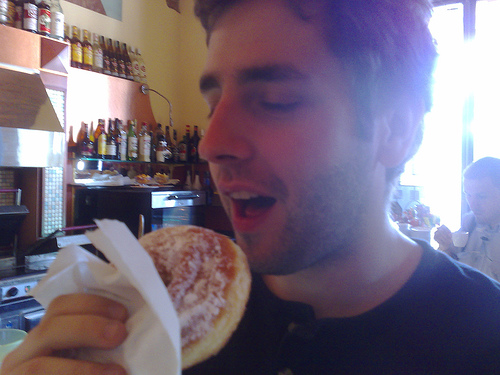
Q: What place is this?
A: It is a restaurant.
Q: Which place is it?
A: It is a restaurant.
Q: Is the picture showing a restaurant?
A: Yes, it is showing a restaurant.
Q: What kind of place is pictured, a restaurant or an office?
A: It is a restaurant.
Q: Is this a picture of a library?
A: No, the picture is showing a restaurant.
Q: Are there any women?
A: No, there are no women.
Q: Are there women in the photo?
A: No, there are no women.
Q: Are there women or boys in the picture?
A: No, there are no women or boys.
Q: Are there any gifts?
A: No, there are no gifts.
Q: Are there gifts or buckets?
A: No, there are no gifts or buckets.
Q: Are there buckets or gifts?
A: No, there are no gifts or buckets.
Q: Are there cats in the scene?
A: No, there are no cats.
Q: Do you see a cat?
A: No, there are no cats.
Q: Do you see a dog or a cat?
A: No, there are no cats or dogs.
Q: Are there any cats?
A: No, there are no cats.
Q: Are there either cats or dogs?
A: No, there are no cats or dogs.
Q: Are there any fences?
A: No, there are no fences.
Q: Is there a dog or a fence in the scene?
A: No, there are no fences or dogs.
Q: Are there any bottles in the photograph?
A: Yes, there is a bottle.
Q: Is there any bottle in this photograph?
A: Yes, there is a bottle.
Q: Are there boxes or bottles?
A: Yes, there is a bottle.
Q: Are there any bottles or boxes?
A: Yes, there is a bottle.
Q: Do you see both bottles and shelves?
A: Yes, there are both a bottle and a shelf.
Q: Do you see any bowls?
A: No, there are no bowls.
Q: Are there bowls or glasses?
A: No, there are no bowls or glasses.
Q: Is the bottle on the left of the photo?
A: Yes, the bottle is on the left of the image.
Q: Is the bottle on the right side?
A: No, the bottle is on the left of the image.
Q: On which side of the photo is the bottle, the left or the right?
A: The bottle is on the left of the image.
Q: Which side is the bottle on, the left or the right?
A: The bottle is on the left of the image.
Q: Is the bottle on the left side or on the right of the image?
A: The bottle is on the left of the image.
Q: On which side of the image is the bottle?
A: The bottle is on the left of the image.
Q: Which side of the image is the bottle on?
A: The bottle is on the left of the image.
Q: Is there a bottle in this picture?
A: Yes, there is a bottle.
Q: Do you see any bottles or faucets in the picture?
A: Yes, there is a bottle.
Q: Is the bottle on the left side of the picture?
A: Yes, the bottle is on the left of the image.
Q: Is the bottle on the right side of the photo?
A: No, the bottle is on the left of the image.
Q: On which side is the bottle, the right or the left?
A: The bottle is on the left of the image.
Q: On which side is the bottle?
A: The bottle is on the left of the image.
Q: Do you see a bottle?
A: Yes, there is a bottle.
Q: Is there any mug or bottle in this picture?
A: Yes, there is a bottle.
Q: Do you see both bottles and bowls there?
A: No, there is a bottle but no bowls.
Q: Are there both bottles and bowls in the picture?
A: No, there is a bottle but no bowls.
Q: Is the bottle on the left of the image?
A: Yes, the bottle is on the left of the image.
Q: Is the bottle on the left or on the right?
A: The bottle is on the left of the image.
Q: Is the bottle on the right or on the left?
A: The bottle is on the left of the image.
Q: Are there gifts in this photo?
A: No, there are no gifts.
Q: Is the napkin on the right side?
A: No, the napkin is on the left of the image.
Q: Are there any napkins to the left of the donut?
A: Yes, there is a napkin to the left of the donut.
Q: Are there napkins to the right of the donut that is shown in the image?
A: No, the napkin is to the left of the donut.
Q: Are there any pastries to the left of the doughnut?
A: No, there is a napkin to the left of the doughnut.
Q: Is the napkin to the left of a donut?
A: Yes, the napkin is to the left of a donut.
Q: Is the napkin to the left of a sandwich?
A: No, the napkin is to the left of a donut.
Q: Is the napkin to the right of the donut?
A: No, the napkin is to the left of the donut.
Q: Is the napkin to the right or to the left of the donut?
A: The napkin is to the left of the donut.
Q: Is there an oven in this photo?
A: Yes, there is an oven.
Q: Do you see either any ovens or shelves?
A: Yes, there is an oven.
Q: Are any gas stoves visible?
A: No, there are no gas stoves.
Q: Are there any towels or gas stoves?
A: No, there are no gas stoves or towels.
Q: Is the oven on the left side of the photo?
A: Yes, the oven is on the left of the image.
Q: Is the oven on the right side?
A: No, the oven is on the left of the image.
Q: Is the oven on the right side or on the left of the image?
A: The oven is on the left of the image.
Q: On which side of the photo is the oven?
A: The oven is on the left of the image.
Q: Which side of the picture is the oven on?
A: The oven is on the left of the image.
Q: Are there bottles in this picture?
A: Yes, there is a bottle.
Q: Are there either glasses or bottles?
A: Yes, there is a bottle.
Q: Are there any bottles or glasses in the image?
A: Yes, there is a bottle.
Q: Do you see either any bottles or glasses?
A: Yes, there is a bottle.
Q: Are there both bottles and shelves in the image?
A: Yes, there are both a bottle and a shelf.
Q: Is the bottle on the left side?
A: Yes, the bottle is on the left of the image.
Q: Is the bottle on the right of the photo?
A: No, the bottle is on the left of the image.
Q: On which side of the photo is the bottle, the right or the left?
A: The bottle is on the left of the image.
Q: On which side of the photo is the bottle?
A: The bottle is on the left of the image.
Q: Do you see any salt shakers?
A: No, there are no salt shakers.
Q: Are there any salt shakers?
A: No, there are no salt shakers.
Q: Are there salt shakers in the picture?
A: No, there are no salt shakers.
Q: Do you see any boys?
A: No, there are no boys.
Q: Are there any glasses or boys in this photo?
A: No, there are no boys or glasses.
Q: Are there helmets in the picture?
A: No, there are no helmets.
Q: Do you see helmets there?
A: No, there are no helmets.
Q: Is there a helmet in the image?
A: No, there are no helmets.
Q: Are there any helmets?
A: No, there are no helmets.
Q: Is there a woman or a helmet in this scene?
A: No, there are no helmets or women.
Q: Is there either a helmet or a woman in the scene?
A: No, there are no helmets or women.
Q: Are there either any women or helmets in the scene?
A: No, there are no helmets or women.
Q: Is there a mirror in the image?
A: No, there are no mirrors.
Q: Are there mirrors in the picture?
A: No, there are no mirrors.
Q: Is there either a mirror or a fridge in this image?
A: No, there are no mirrors or refrigerators.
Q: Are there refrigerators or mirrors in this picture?
A: No, there are no mirrors or refrigerators.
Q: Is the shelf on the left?
A: Yes, the shelf is on the left of the image.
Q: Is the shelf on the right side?
A: No, the shelf is on the left of the image.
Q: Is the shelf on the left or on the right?
A: The shelf is on the left of the image.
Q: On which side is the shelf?
A: The shelf is on the left of the image.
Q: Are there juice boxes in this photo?
A: No, there are no juice boxes.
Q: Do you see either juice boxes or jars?
A: No, there are no juice boxes or jars.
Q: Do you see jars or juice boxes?
A: No, there are no juice boxes or jars.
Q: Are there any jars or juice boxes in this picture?
A: No, there are no juice boxes or jars.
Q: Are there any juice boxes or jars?
A: No, there are no juice boxes or jars.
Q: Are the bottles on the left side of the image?
A: Yes, the bottles are on the left of the image.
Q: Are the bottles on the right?
A: No, the bottles are on the left of the image.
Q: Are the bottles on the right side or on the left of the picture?
A: The bottles are on the left of the image.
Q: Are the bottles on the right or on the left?
A: The bottles are on the left of the image.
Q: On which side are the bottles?
A: The bottles are on the left of the image.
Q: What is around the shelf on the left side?
A: The bottles are around the shelf.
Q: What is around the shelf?
A: The bottles are around the shelf.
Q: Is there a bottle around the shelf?
A: Yes, there are bottles around the shelf.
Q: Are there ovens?
A: Yes, there is an oven.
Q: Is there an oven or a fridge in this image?
A: Yes, there is an oven.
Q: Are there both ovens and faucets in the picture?
A: No, there is an oven but no faucets.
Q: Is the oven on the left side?
A: Yes, the oven is on the left of the image.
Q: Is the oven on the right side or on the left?
A: The oven is on the left of the image.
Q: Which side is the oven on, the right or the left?
A: The oven is on the left of the image.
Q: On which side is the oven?
A: The oven is on the left of the image.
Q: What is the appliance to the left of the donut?
A: The appliance is an oven.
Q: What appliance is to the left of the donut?
A: The appliance is an oven.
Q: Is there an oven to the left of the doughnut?
A: Yes, there is an oven to the left of the doughnut.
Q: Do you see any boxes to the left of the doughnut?
A: No, there is an oven to the left of the doughnut.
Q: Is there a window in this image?
A: Yes, there are windows.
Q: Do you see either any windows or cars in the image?
A: Yes, there are windows.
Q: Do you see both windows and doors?
A: No, there are windows but no doors.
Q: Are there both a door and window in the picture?
A: No, there are windows but no doors.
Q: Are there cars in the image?
A: No, there are no cars.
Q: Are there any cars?
A: No, there are no cars.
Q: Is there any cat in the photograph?
A: No, there are no cats.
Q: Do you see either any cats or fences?
A: No, there are no cats or fences.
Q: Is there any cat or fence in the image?
A: No, there are no cats or fences.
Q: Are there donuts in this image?
A: Yes, there is a donut.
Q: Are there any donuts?
A: Yes, there is a donut.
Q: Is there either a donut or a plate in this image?
A: Yes, there is a donut.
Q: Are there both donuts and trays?
A: No, there is a donut but no trays.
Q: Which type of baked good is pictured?
A: The baked good is a donut.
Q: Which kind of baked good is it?
A: The food is a donut.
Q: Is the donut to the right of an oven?
A: Yes, the donut is to the right of an oven.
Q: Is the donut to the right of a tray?
A: No, the donut is to the right of an oven.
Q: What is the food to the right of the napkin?
A: The food is a donut.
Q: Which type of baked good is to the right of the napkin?
A: The food is a donut.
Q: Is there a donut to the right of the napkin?
A: Yes, there is a donut to the right of the napkin.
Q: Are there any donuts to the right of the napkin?
A: Yes, there is a donut to the right of the napkin.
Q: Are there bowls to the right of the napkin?
A: No, there is a donut to the right of the napkin.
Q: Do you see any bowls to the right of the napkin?
A: No, there is a donut to the right of the napkin.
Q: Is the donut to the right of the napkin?
A: Yes, the donut is to the right of the napkin.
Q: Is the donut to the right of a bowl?
A: No, the donut is to the right of the napkin.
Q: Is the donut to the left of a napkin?
A: No, the donut is to the right of a napkin.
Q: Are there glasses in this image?
A: No, there are no glasses.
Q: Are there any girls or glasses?
A: No, there are no glasses or girls.